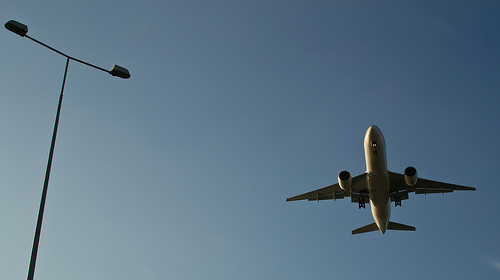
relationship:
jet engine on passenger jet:
[337, 171, 358, 206] [286, 123, 478, 233]